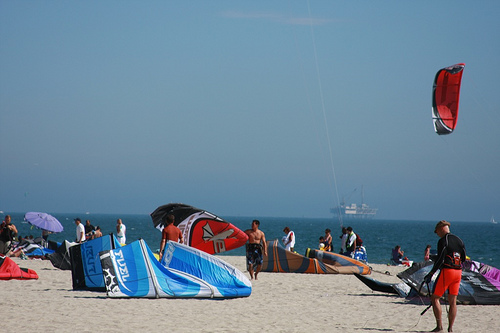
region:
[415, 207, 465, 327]
Man walking on beach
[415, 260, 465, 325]
Man with orange shorts on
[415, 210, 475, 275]
Man with black tee shirt on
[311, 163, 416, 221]
Ship cruising on ocean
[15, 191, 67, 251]
Light purple umbrella open on beach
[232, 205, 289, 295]
Man walking foreward on beach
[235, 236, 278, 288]
Black swim shorts on man walking foreward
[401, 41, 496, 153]
Black, orange and white kite floating in the sky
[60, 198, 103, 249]
Man with white tee shirt on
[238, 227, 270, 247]
Chest of man walking forward on beach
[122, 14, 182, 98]
this is the sky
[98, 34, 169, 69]
the sky is blue in color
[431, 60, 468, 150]
this is a kite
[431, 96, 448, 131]
the kite is red and black in color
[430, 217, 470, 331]
this is a man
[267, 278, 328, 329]
this is a sand in the beach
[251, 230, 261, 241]
the man is bare chested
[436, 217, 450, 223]
this is a cap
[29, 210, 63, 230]
this is an umbrella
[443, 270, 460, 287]
the man is wearing a orange shorts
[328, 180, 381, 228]
oil rig in the background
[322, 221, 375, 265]
people flying big kites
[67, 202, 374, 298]
kites are on the sand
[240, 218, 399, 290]
people are on the sand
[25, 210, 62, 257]
umbrella is over people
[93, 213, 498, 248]
water is very blue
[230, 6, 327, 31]
sky has one small cloud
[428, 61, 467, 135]
a red kite in the air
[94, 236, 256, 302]
a blue kite on the sand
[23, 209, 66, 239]
a purple umbrella near people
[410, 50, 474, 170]
orange windsail in the blue sky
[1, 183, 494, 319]
wind surfers on a beach getting ready to go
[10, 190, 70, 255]
person underneath a lavender umbrella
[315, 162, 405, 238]
ship on a blue ocean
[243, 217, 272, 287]
shirtless man in swim trunks on the beach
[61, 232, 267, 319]
blue and white wind sail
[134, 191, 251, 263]
orange and black wind sail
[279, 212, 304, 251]
man in white shirt on the beach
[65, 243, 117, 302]
black and blue wind sail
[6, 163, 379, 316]
wind sailors on the beach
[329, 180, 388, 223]
the ship in the background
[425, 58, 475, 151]
the kite in the sky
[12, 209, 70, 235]
the blue umbrella in the background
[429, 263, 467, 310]
The red shorts are tight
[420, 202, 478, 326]
the man is flying a kite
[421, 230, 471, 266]
the black shirt of the man flying the kite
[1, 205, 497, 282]
the blue ocean water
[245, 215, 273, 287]
the shirtless man in shorts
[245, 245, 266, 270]
the shorts of the shirtless man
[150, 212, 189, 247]
The man in the red t-shirt